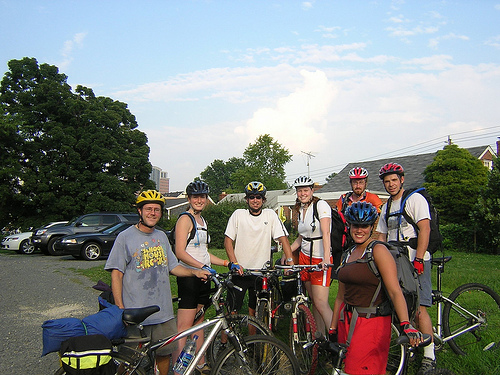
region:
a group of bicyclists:
[89, 158, 498, 368]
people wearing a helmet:
[128, 157, 444, 233]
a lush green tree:
[16, 94, 127, 200]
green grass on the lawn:
[456, 246, 499, 284]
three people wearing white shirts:
[185, 206, 333, 261]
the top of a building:
[151, 159, 181, 192]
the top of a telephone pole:
[288, 144, 333, 169]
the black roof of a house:
[348, 142, 498, 167]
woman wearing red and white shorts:
[297, 251, 335, 286]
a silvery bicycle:
[126, 264, 244, 374]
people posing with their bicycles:
[50, 152, 495, 372]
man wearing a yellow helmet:
[127, 176, 167, 226]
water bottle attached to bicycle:
[163, 320, 274, 373]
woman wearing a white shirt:
[285, 166, 330, 257]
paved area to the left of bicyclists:
[0, 162, 245, 367]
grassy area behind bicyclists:
[116, 235, 491, 370]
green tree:
[420, 136, 495, 261]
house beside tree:
[281, 138, 491, 249]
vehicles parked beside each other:
[5, 201, 143, 261]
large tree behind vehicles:
[0, 55, 155, 257]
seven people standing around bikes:
[106, 158, 453, 373]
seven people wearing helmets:
[104, 162, 446, 374]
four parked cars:
[1, 204, 168, 266]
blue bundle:
[36, 299, 136, 357]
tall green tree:
[422, 135, 491, 256]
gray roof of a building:
[326, 134, 487, 192]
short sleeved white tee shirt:
[223, 206, 287, 271]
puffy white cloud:
[233, 68, 333, 165]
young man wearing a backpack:
[377, 163, 449, 366]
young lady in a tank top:
[172, 180, 222, 374]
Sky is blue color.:
[78, 11, 245, 59]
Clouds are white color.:
[241, 91, 341, 129]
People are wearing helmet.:
[128, 161, 436, 272]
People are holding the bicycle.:
[129, 173, 436, 371]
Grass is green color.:
[453, 255, 499, 278]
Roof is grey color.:
[338, 158, 473, 195]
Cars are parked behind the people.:
[18, 214, 166, 266]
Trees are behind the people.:
[13, 93, 248, 196]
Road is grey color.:
[25, 268, 75, 315]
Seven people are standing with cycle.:
[116, 174, 456, 285]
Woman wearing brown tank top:
[332, 203, 409, 373]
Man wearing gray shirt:
[107, 181, 211, 373]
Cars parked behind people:
[1, 211, 146, 267]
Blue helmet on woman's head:
[346, 199, 388, 244]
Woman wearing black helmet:
[171, 165, 221, 352]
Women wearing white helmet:
[284, 167, 338, 329]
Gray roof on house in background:
[318, 141, 485, 203]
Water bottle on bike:
[168, 323, 203, 370]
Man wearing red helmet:
[375, 158, 436, 291]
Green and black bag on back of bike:
[47, 331, 124, 373]